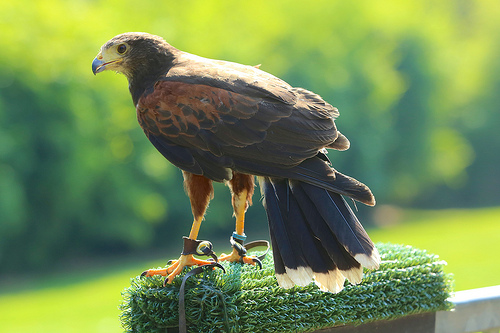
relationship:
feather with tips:
[298, 181, 381, 271] [268, 251, 388, 285]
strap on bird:
[184, 235, 208, 259] [90, 32, 385, 297]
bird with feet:
[90, 32, 385, 297] [150, 217, 280, 269]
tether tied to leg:
[182, 238, 211, 319] [181, 170, 215, 258]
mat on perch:
[125, 240, 448, 331] [126, 243, 446, 327]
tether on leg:
[174, 235, 222, 333] [176, 165, 213, 252]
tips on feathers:
[273, 241, 380, 297] [250, 170, 379, 294]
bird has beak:
[90, 32, 384, 299] [90, 54, 101, 72]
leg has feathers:
[222, 170, 257, 252] [223, 161, 258, 215]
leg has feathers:
[172, 167, 212, 257] [177, 163, 215, 223]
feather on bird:
[289, 156, 379, 210] [90, 32, 384, 299]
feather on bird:
[298, 181, 381, 271] [90, 32, 384, 299]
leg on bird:
[181, 170, 215, 258] [90, 32, 384, 299]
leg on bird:
[225, 170, 255, 252] [90, 32, 384, 299]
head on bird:
[91, 30, 171, 81] [90, 32, 385, 297]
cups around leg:
[167, 238, 270, 249] [176, 214, 261, 231]